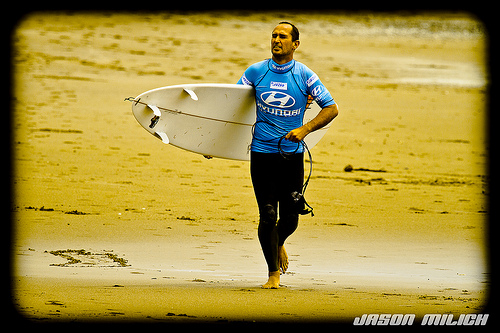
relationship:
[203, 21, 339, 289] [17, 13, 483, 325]
guy on beach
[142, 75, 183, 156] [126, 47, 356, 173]
fin on board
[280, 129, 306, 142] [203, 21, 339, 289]
hand of a guy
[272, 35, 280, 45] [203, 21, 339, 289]
nose of a guy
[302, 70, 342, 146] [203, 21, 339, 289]
arm of a guy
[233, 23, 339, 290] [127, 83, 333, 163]
guy carrying surfboard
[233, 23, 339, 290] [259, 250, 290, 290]
guy wearing shoes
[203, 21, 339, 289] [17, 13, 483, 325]
guy running on beach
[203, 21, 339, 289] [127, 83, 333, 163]
guy carrying surfboard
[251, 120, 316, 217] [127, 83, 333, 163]
cable of surfboard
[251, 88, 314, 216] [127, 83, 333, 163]
cable with surfboard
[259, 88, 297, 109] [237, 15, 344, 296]
logo on shirt